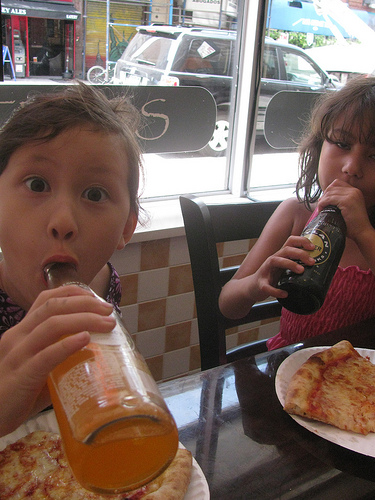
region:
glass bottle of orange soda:
[8, 263, 180, 489]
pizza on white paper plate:
[0, 408, 174, 498]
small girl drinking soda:
[0, 74, 174, 483]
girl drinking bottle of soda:
[261, 55, 371, 310]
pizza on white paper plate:
[275, 334, 367, 429]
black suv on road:
[128, 21, 354, 171]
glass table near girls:
[177, 346, 325, 497]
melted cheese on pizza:
[326, 356, 373, 422]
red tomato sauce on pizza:
[301, 382, 324, 410]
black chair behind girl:
[176, 193, 312, 376]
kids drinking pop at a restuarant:
[19, 84, 368, 387]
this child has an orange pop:
[15, 116, 176, 387]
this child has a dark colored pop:
[258, 111, 374, 331]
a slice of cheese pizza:
[262, 337, 374, 465]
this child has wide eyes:
[14, 127, 128, 230]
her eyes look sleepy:
[314, 116, 374, 169]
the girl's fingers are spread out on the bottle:
[240, 225, 333, 308]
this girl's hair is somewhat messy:
[9, 85, 162, 194]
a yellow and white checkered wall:
[122, 254, 213, 370]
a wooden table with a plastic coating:
[174, 375, 302, 498]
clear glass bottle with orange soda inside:
[32, 255, 182, 496]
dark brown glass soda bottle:
[272, 178, 351, 315]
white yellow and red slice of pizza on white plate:
[277, 337, 373, 436]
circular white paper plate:
[268, 337, 374, 461]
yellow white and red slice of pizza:
[0, 424, 196, 498]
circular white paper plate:
[0, 396, 213, 498]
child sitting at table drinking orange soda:
[0, 76, 155, 445]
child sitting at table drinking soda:
[215, 73, 374, 367]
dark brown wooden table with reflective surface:
[0, 304, 373, 499]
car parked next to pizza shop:
[103, 19, 373, 159]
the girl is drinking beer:
[226, 85, 370, 331]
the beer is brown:
[280, 209, 346, 316]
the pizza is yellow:
[298, 338, 374, 433]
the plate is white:
[275, 342, 373, 466]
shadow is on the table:
[239, 365, 286, 450]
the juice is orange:
[36, 275, 181, 497]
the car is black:
[152, 44, 332, 157]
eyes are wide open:
[24, 173, 116, 215]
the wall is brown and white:
[143, 286, 188, 347]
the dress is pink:
[339, 263, 373, 314]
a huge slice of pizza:
[286, 337, 372, 429]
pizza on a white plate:
[274, 340, 373, 458]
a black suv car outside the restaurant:
[115, 19, 348, 151]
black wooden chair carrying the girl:
[176, 194, 289, 370]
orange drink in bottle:
[39, 260, 179, 492]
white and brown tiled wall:
[108, 230, 322, 382]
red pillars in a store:
[7, 15, 76, 78]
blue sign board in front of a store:
[1, 42, 17, 82]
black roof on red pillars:
[1, 1, 82, 75]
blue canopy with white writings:
[261, 1, 374, 34]